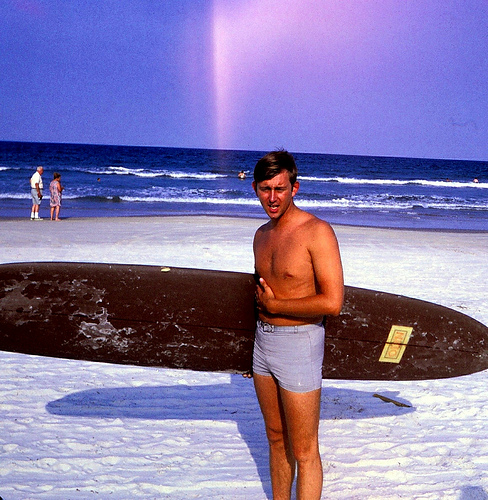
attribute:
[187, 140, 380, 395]
surfer — gray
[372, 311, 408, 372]
sticker — yellow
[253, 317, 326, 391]
swim trunks — gray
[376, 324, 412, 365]
sticker — yellow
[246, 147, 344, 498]
man — shirtless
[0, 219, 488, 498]
sand — white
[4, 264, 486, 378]
surfboard — brown, long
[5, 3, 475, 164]
sky — clear, blue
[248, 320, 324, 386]
shorts — tight